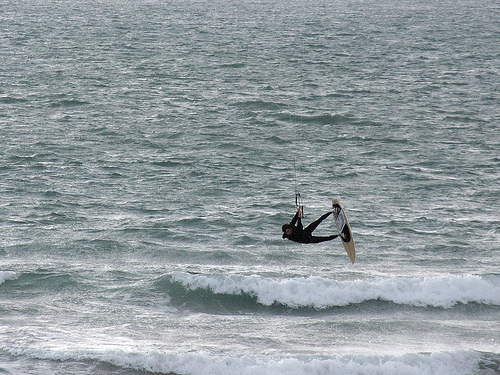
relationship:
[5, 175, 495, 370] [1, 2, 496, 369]
waves on water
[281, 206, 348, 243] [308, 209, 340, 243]
person has legs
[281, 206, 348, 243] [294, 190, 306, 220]
person holding handle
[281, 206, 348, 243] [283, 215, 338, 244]
person wearing a wetsuit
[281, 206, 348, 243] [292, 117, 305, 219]
person grabbing strings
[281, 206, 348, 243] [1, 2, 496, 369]
person looking down at water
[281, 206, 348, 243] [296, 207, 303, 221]
person has hands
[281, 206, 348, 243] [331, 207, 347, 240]
person has feet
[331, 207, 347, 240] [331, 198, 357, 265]
feet attached to surfboard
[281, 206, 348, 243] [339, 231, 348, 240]
person has a right foot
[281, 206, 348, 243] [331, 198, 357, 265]
person on a kite surfboard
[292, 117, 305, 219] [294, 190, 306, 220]
strings to kite handle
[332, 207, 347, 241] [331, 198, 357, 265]
foot straps on surfboard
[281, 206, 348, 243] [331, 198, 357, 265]
person attached to surfboard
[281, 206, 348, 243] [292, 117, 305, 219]
person holding kite strings